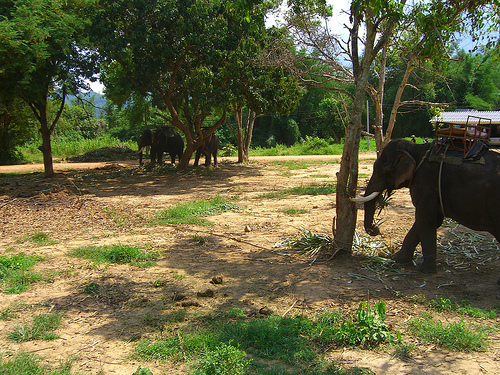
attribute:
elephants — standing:
[107, 120, 248, 158]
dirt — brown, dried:
[48, 178, 218, 218]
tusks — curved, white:
[340, 186, 378, 202]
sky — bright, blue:
[257, 0, 491, 44]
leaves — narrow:
[425, 16, 432, 66]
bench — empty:
[424, 121, 492, 152]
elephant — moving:
[353, 125, 500, 254]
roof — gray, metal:
[440, 109, 498, 122]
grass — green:
[198, 311, 331, 348]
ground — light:
[43, 272, 457, 367]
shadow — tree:
[162, 219, 323, 304]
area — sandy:
[65, 165, 245, 219]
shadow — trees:
[74, 168, 240, 203]